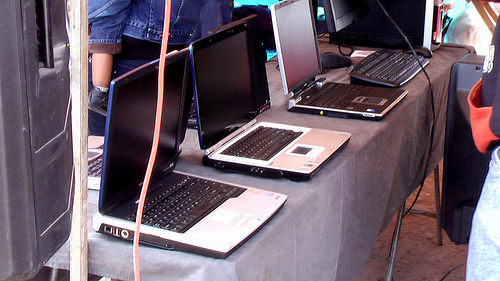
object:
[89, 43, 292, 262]
laptop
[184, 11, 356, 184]
laptop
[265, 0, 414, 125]
laptop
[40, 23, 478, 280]
table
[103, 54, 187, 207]
screen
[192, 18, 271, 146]
screen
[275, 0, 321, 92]
screen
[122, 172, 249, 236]
keyboard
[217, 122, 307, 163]
keyboard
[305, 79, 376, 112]
keyboard